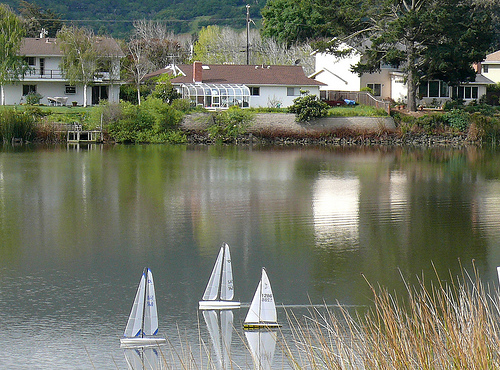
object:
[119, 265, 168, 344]
sailboat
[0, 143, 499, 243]
water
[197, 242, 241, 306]
sailboat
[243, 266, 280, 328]
sailboat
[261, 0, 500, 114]
tree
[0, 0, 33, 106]
tree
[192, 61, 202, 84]
chimney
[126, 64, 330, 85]
roof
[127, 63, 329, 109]
house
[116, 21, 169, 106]
tree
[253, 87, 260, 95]
window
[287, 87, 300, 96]
window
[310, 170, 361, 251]
reflection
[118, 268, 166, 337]
sail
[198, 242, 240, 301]
sail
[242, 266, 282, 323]
sail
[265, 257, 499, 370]
grass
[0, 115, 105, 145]
dock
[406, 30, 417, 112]
trunk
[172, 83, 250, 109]
greenhouse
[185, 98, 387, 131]
backyard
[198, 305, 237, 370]
reflection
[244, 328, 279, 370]
reflection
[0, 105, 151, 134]
backyard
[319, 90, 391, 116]
fence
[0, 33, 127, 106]
house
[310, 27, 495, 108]
house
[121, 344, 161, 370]
reflection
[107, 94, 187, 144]
bush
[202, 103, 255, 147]
bush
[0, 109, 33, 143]
bush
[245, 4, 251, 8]
light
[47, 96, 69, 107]
barbeque